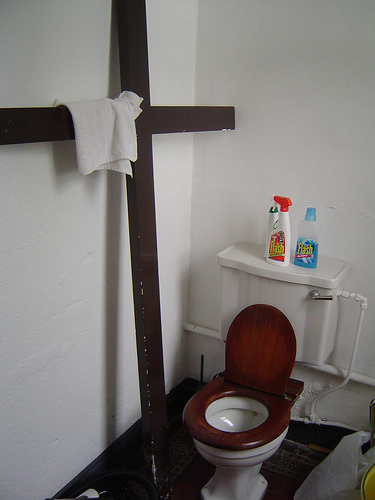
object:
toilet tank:
[215, 241, 352, 366]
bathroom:
[1, 0, 374, 498]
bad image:
[218, 302, 305, 401]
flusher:
[308, 288, 334, 303]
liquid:
[293, 240, 318, 269]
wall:
[0, 0, 200, 500]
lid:
[223, 303, 299, 399]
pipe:
[310, 309, 369, 417]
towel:
[50, 89, 145, 180]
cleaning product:
[263, 205, 279, 259]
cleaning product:
[265, 193, 292, 268]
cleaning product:
[293, 207, 321, 269]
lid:
[216, 240, 352, 290]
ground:
[81, 408, 375, 500]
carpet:
[120, 410, 334, 500]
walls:
[183, 0, 375, 457]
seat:
[182, 302, 306, 452]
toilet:
[180, 240, 352, 500]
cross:
[0, 0, 240, 500]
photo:
[4, 2, 373, 495]